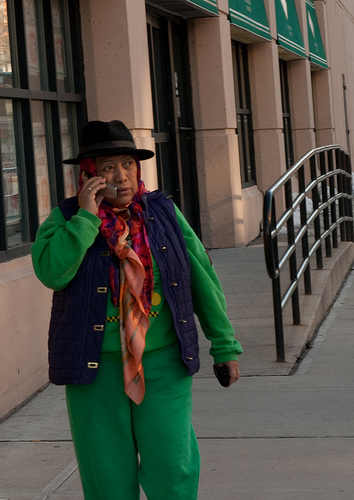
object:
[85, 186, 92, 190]
ring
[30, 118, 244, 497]
woman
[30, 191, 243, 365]
shirt